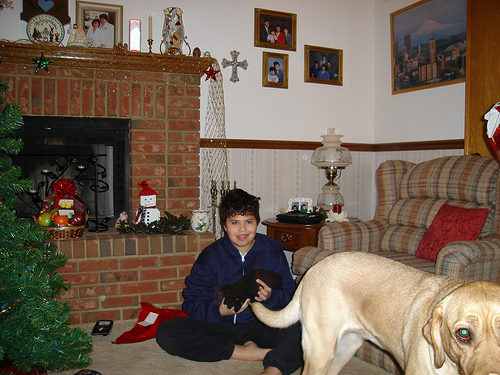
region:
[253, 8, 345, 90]
group of three family photographs on wall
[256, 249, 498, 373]
yellow labrador retriever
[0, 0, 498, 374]
Christmastime in the living room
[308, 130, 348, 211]
globe style table lamp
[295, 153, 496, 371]
overstuffed plaid highback armchair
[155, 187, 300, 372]
young boy holding small animal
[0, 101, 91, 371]
Christmas tree with no decorations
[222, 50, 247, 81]
cross on wall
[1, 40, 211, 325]
large brick fireplace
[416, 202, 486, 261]
square red pillow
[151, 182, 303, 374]
a kid poses for a picture in the family living room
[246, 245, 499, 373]
the kid's dog looks like a laborador retriever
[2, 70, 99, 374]
the Christmas tree off to one side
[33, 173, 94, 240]
someone gave the family a fruit basket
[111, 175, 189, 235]
a Christmas snowman decoration on the fireplace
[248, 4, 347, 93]
family pictures on the wall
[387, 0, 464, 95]
a picture of a cityscape on the wall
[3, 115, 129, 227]
the fireplace is not lit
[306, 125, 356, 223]
pretty glass lamp on the table next to the sofa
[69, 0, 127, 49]
a family picture on the mantel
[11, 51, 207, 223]
A fireplace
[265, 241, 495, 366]
A brown dog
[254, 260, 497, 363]
The dog is looking at the camera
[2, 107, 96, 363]
A Christmas tree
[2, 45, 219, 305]
Fireplace is made of brick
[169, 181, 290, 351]
Boy smiling at the camera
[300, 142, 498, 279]
A reclining chair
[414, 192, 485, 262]
Red cushion on the chair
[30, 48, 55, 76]
A green star on the fireplace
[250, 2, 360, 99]
Family pictures on the wall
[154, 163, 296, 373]
A person sitting on the carpt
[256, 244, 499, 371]
A cream dog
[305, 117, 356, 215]
Cream and gold table lamp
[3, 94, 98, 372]
Part of an artificial christmas tree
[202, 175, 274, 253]
A boy with short black hair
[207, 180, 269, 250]
A boy with short hair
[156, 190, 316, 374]
A boy sitting down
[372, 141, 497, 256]
A checkered sofa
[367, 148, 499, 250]
A checkered sofa with a red throw pillow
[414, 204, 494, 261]
Red throwpillow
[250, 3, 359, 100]
pictures in the wall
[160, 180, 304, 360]
boy wearing blue jacket sitting in the floor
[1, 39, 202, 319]
Brick fire place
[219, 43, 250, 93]
small cross in the wall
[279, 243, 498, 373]
brown dog standing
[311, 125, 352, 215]
glass lamp shade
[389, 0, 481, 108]
painting on the side of the wall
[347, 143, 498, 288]
brown stripes chair with pillow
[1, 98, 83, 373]
Christmas tree on the side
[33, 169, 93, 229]
basket of fruits in the fire place